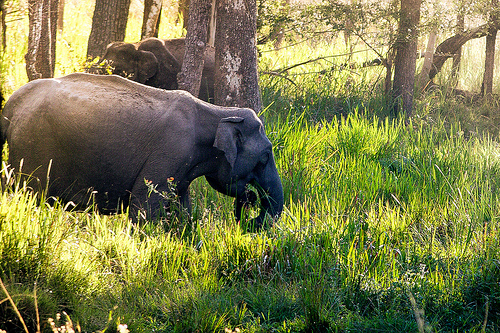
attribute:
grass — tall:
[0, 119, 495, 326]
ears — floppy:
[212, 113, 244, 173]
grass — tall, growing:
[6, 64, 499, 326]